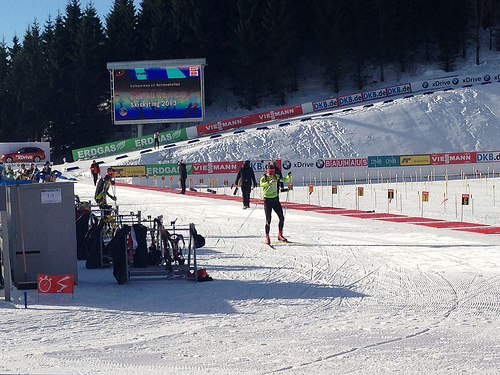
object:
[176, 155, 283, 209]
skiers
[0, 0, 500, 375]
course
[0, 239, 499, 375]
path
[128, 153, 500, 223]
barrier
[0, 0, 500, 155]
trees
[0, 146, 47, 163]
car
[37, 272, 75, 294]
sign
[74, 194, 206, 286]
racks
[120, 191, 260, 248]
sidelines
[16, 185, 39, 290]
broom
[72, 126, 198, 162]
advertisement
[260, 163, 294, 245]
person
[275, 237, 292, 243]
skis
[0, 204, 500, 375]
tracks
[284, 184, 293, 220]
pole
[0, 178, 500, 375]
ground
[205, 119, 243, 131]
writing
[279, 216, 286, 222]
knee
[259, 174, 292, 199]
shirt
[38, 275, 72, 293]
image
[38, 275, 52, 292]
clock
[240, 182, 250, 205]
pants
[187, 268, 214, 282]
boot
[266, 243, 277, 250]
ski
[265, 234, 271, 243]
foot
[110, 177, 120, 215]
crutch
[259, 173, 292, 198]
top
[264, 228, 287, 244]
boots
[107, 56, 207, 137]
billboard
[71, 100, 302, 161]
banner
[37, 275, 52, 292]
stopwatch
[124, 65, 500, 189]
hill